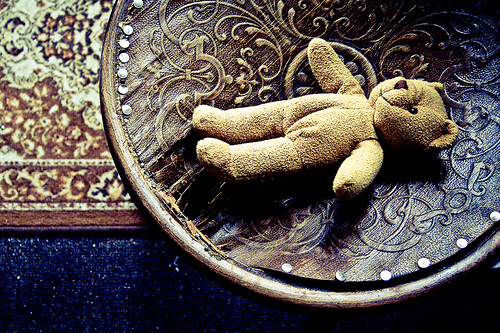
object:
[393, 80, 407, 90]
nose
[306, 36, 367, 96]
arm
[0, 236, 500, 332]
carpet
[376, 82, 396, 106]
mouth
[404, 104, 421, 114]
eye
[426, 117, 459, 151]
ear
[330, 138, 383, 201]
left arm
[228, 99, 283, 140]
leg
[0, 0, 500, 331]
rug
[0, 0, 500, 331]
floor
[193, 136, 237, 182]
foot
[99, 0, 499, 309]
handle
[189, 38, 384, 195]
body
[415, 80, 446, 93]
ear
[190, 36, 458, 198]
bear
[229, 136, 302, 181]
leg